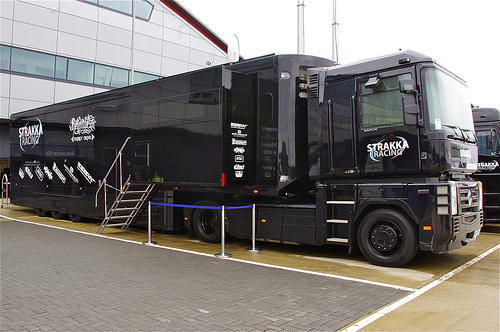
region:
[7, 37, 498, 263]
LARGE BLACK TOURING TRUCK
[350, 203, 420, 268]
FRONT RIGHT TIRE OF THE TRUCK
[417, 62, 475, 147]
THE FRONT WINDSHIELD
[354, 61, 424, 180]
THE PASSENGER SIDE DOOR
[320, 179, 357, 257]
PASSENGER SIDE STEPS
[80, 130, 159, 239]
METAL STEPS LEADING INTO CAMPER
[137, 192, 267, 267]
SILVER POLES WITH BLUE BARRIER ROPES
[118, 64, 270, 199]
THE CAMPER'S SIDE PULL OUT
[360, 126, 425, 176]
THE LOGO PAINTED ON THE PASSENGER DOOR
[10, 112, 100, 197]
THE LOGO AND SPONSORS ON THE BACK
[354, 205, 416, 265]
A front right tire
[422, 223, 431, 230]
A light on a truck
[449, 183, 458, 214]
Headlight on a truck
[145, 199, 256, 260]
A small barricade using rods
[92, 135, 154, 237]
A pair of stairs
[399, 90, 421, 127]
A side mirror on a truck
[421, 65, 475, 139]
A windshield on a truck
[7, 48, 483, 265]
A very big truck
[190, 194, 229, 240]
Side wheel on a truck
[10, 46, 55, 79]
Window on a building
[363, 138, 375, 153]
white letter on truck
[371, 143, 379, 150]
white letter on truck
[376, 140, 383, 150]
white letter on truck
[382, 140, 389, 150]
white letter on truck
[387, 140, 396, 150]
white letter on truck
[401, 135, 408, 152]
white letter on truck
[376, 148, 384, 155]
white letter on truck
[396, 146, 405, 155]
white letter on truck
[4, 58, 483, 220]
black and white truck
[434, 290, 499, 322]
lot is light brown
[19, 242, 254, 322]
sidewalk is light grey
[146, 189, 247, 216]
blue cords between poles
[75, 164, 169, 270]
grey steps to truck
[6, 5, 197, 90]
white building behind truck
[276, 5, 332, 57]
grey poles behind truck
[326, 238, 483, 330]
white lines on lot